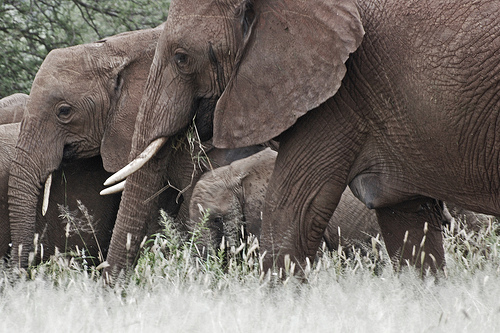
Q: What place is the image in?
A: It is at the field.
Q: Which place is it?
A: It is a field.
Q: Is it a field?
A: Yes, it is a field.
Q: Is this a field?
A: Yes, it is a field.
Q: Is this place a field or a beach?
A: It is a field.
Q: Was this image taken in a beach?
A: No, the picture was taken in a field.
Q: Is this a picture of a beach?
A: No, the picture is showing a field.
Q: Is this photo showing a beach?
A: No, the picture is showing a field.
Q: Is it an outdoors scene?
A: Yes, it is outdoors.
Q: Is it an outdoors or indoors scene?
A: It is outdoors.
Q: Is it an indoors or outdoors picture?
A: It is outdoors.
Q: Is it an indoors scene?
A: No, it is outdoors.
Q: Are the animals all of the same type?
A: Yes, all the animals are elephants.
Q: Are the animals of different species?
A: No, all the animals are elephants.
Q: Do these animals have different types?
A: No, all the animals are elephants.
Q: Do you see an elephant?
A: Yes, there is an elephant.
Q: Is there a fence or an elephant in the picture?
A: Yes, there is an elephant.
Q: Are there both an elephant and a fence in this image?
A: No, there is an elephant but no fences.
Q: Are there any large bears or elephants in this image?
A: Yes, there is a large elephant.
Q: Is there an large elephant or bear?
A: Yes, there is a large elephant.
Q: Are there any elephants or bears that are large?
A: Yes, the elephant is large.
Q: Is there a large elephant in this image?
A: Yes, there is a large elephant.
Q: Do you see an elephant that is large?
A: Yes, there is an elephant that is large.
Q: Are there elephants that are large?
A: Yes, there is an elephant that is large.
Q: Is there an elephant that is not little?
A: Yes, there is a large elephant.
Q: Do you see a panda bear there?
A: No, there are no pandas.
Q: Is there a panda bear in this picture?
A: No, there are no pandas.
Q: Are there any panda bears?
A: No, there are no panda bears.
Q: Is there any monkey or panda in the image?
A: No, there are no pandas or monkeys.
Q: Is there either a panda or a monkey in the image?
A: No, there are no pandas or monkeys.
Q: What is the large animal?
A: The animal is an elephant.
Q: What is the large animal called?
A: The animal is an elephant.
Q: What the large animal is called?
A: The animal is an elephant.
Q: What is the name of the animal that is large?
A: The animal is an elephant.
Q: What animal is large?
A: The animal is an elephant.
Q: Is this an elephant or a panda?
A: This is an elephant.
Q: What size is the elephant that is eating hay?
A: The elephant is large.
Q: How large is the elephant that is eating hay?
A: The elephant is large.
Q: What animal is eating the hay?
A: The elephant is eating the hay.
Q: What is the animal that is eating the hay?
A: The animal is an elephant.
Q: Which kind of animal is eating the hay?
A: The animal is an elephant.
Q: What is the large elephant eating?
A: The elephant is eating hay.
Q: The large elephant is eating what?
A: The elephant is eating hay.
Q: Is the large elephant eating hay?
A: Yes, the elephant is eating hay.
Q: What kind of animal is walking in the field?
A: The animal is an elephant.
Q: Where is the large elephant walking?
A: The elephant is walking in the field.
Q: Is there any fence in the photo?
A: No, there are no fences.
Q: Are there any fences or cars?
A: No, there are no fences or cars.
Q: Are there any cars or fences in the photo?
A: No, there are no fences or cars.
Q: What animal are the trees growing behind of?
A: The trees are growing behind the elephant.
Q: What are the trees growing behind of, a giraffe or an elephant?
A: The trees are growing behind an elephant.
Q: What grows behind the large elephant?
A: The trees grow behind the elephant.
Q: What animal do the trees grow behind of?
A: The trees grow behind the elephant.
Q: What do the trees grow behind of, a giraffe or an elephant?
A: The trees grow behind an elephant.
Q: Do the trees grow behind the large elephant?
A: Yes, the trees grow behind the elephant.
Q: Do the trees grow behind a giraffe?
A: No, the trees grow behind the elephant.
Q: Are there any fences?
A: No, there are no fences.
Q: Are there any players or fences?
A: No, there are no fences or players.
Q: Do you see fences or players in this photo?
A: No, there are no fences or players.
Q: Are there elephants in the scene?
A: Yes, there is an elephant.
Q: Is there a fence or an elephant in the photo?
A: Yes, there is an elephant.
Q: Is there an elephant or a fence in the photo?
A: Yes, there is an elephant.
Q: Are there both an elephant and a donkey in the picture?
A: No, there is an elephant but no donkeys.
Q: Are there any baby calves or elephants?
A: Yes, there is a baby elephant.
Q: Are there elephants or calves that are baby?
A: Yes, the elephant is a baby.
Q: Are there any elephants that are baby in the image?
A: Yes, there is a baby elephant.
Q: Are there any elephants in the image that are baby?
A: Yes, there is an elephant that is a baby.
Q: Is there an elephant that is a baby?
A: Yes, there is an elephant that is a baby.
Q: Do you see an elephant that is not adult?
A: Yes, there is an baby elephant.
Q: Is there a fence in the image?
A: No, there are no fences.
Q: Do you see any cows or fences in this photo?
A: No, there are no fences or cows.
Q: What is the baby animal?
A: The animal is an elephant.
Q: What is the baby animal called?
A: The animal is an elephant.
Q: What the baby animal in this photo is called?
A: The animal is an elephant.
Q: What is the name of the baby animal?
A: The animal is an elephant.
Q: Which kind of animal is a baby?
A: The animal is an elephant.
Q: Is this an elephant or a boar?
A: This is an elephant.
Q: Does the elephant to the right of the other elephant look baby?
A: Yes, the elephant is a baby.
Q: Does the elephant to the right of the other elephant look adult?
A: No, the elephant is a baby.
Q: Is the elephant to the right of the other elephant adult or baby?
A: The elephant is a baby.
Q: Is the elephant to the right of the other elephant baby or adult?
A: The elephant is a baby.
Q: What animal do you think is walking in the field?
A: The elephant is walking in the field.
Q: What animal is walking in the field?
A: The elephant is walking in the field.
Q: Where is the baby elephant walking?
A: The elephant is walking in the field.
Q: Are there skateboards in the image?
A: No, there are no skateboards.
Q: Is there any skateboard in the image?
A: No, there are no skateboards.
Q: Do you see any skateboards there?
A: No, there are no skateboards.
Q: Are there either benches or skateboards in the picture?
A: No, there are no skateboards or benches.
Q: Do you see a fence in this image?
A: No, there are no fences.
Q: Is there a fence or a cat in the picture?
A: No, there are no fences or cats.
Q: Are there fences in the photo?
A: No, there are no fences.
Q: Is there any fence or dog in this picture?
A: No, there are no fences or dogs.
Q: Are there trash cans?
A: No, there are no trash cans.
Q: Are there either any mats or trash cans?
A: No, there are no trash cans or mats.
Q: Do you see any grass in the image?
A: Yes, there is grass.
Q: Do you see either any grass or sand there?
A: Yes, there is grass.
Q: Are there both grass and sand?
A: No, there is grass but no sand.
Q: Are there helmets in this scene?
A: No, there are no helmets.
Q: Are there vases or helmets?
A: No, there are no helmets or vases.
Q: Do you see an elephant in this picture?
A: Yes, there is an elephant.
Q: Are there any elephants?
A: Yes, there is an elephant.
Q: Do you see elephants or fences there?
A: Yes, there is an elephant.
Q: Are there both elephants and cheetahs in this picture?
A: No, there is an elephant but no cheetahs.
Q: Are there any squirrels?
A: No, there are no squirrels.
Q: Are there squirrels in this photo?
A: No, there are no squirrels.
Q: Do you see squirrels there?
A: No, there are no squirrels.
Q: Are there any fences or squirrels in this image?
A: No, there are no squirrels or fences.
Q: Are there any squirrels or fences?
A: No, there are no squirrels or fences.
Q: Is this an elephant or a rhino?
A: This is an elephant.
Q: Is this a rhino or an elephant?
A: This is an elephant.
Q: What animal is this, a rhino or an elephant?
A: This is an elephant.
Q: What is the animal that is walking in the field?
A: The animal is an elephant.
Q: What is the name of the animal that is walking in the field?
A: The animal is an elephant.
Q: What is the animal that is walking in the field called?
A: The animal is an elephant.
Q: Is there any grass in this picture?
A: Yes, there is grass.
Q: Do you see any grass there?
A: Yes, there is grass.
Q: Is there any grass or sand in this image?
A: Yes, there is grass.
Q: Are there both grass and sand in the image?
A: No, there is grass but no sand.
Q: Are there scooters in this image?
A: No, there are no scooters.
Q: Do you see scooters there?
A: No, there are no scooters.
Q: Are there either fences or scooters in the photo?
A: No, there are no scooters or fences.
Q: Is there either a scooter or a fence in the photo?
A: No, there are no scooters or fences.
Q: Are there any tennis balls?
A: No, there are no tennis balls.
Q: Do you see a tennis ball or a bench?
A: No, there are no tennis balls or benches.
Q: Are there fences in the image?
A: No, there are no fences.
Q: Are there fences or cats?
A: No, there are no fences or cats.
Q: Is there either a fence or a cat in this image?
A: No, there are no fences or cats.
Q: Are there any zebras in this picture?
A: No, there are no zebras.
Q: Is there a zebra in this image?
A: No, there are no zebras.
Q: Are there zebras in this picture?
A: No, there are no zebras.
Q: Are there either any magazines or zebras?
A: No, there are no zebras or magazines.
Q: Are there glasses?
A: No, there are no glasses.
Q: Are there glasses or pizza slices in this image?
A: No, there are no glasses or pizza slices.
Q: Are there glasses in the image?
A: No, there are no glasses.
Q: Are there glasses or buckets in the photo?
A: No, there are no glasses or buckets.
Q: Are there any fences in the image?
A: No, there are no fences.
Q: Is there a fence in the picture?
A: No, there are no fences.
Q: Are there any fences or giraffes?
A: No, there are no fences or giraffes.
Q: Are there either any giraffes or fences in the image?
A: No, there are no fences or giraffes.